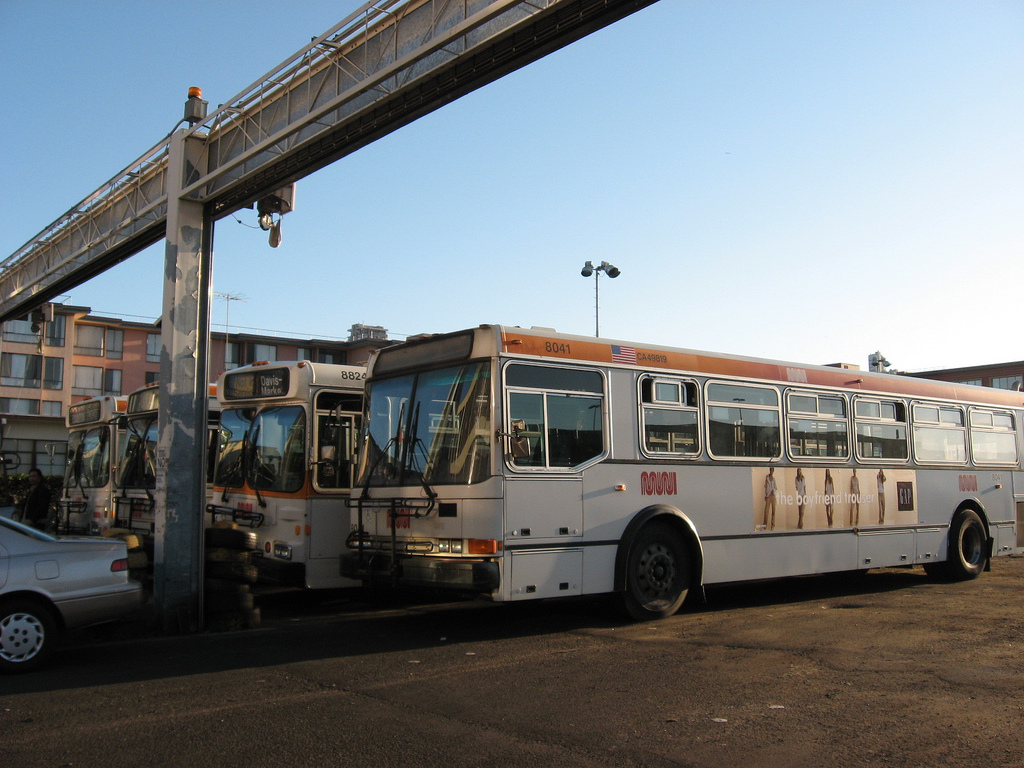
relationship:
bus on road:
[351, 332, 1019, 627] [4, 550, 1018, 764]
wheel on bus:
[616, 519, 705, 615] [354, 297, 1009, 624]